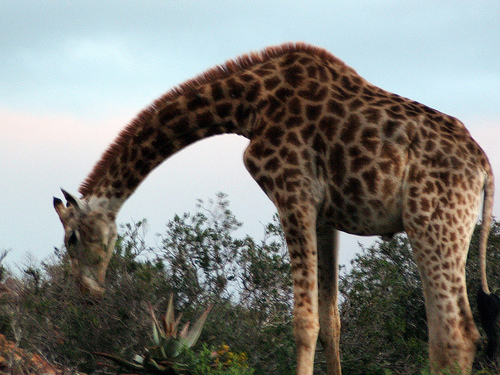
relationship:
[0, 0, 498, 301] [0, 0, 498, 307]
clouds in sky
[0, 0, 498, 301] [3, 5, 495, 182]
clouds in sky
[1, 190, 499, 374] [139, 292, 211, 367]
foliage in bunch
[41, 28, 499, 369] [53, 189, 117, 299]
animal has head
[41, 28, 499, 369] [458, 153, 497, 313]
animal has tail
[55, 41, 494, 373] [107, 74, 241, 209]
giraffe has neck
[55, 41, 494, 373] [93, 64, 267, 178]
giraffe has hair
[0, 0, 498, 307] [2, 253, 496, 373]
sky above land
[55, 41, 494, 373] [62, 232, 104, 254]
giraffe has eye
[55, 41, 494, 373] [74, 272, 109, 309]
giraffe has nose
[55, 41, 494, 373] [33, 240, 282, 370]
giraffe eats plants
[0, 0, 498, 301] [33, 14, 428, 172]
clouds in sky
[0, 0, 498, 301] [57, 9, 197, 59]
clouds in sky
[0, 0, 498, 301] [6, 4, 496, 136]
clouds in sky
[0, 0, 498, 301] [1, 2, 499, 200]
clouds in sky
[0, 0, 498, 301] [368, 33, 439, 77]
clouds in sky